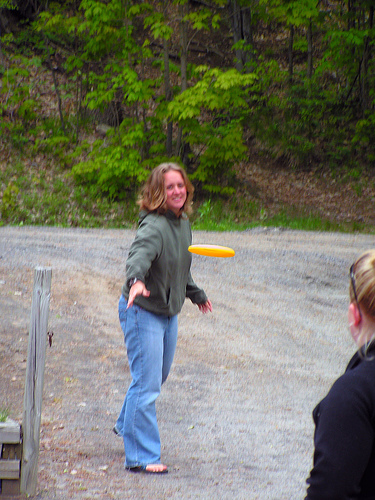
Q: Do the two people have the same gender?
A: Yes, all the people are female.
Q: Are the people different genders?
A: No, all the people are female.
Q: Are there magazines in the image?
A: No, there are no magazines.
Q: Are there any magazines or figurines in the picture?
A: No, there are no magazines or figurines.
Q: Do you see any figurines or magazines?
A: No, there are no magazines or figurines.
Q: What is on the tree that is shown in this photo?
A: The leaves are on the tree.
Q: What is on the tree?
A: The leaves are on the tree.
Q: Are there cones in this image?
A: No, there are no cones.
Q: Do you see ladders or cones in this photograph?
A: No, there are no cones or ladders.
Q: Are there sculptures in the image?
A: No, there are no sculptures.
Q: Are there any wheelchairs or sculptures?
A: No, there are no sculptures or wheelchairs.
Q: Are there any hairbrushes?
A: No, there are no hairbrushes.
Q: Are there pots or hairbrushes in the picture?
A: No, there are no hairbrushes or pots.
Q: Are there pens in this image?
A: No, there are no pens.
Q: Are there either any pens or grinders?
A: No, there are no pens or grinders.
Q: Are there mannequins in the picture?
A: No, there are no mannequins.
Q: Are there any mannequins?
A: No, there are no mannequins.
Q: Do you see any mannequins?
A: No, there are no mannequins.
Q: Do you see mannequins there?
A: No, there are no mannequins.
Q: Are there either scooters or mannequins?
A: No, there are no mannequins or scooters.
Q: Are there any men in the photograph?
A: No, there are no men.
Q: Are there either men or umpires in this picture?
A: No, there are no men or umpires.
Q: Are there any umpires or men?
A: No, there are no men or umpires.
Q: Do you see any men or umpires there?
A: No, there are no men or umpires.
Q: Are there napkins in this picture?
A: No, there are no napkins.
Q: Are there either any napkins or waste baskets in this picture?
A: No, there are no napkins or waste baskets.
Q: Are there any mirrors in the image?
A: No, there are no mirrors.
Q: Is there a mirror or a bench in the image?
A: No, there are no mirrors or benches.